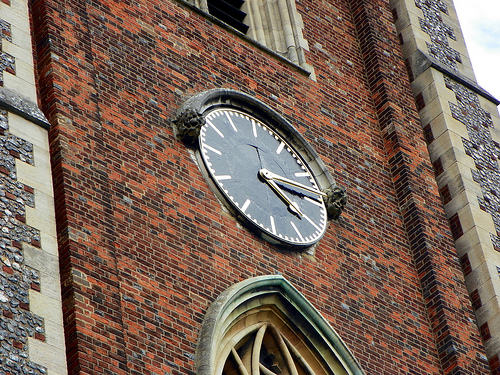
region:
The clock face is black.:
[179, 106, 332, 233]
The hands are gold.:
[257, 168, 318, 220]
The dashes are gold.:
[193, 100, 330, 239]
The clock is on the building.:
[150, 66, 353, 253]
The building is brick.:
[40, 6, 470, 373]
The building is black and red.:
[45, 7, 478, 373]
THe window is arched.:
[178, 266, 353, 373]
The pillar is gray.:
[390, 2, 496, 296]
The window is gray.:
[183, 0, 310, 72]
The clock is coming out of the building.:
[164, 63, 375, 275]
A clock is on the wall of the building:
[162, 66, 357, 250]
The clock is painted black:
[172, 90, 352, 254]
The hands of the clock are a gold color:
[245, 152, 332, 218]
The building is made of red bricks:
[80, 66, 192, 328]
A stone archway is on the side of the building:
[145, 263, 375, 373]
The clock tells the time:
[198, 92, 335, 247]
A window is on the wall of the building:
[200, 1, 318, 76]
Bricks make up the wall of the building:
[92, 183, 184, 268]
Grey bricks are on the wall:
[21, 124, 51, 365]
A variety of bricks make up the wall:
[83, 136, 189, 315]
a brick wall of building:
[59, 17, 177, 116]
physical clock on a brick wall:
[184, 75, 356, 247]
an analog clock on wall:
[189, 90, 336, 250]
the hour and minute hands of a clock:
[254, 163, 328, 221]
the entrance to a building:
[199, 264, 386, 372]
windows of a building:
[137, 3, 324, 80]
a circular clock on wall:
[163, 62, 359, 256]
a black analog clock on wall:
[171, 70, 354, 256]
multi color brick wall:
[79, 122, 167, 274]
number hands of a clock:
[184, 94, 341, 246]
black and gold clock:
[184, 90, 337, 249]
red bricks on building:
[123, 226, 193, 276]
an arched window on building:
[188, 268, 378, 373]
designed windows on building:
[221, 318, 328, 373]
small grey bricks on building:
[476, 158, 498, 190]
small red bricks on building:
[0, 263, 17, 276]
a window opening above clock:
[165, 1, 312, 50]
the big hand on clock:
[259, 170, 324, 195]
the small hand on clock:
[275, 190, 303, 212]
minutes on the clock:
[274, 141, 287, 158]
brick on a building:
[433, 145, 483, 172]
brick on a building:
[433, 160, 478, 188]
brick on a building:
[445, 176, 492, 199]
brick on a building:
[425, 109, 478, 141]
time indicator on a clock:
[246, 113, 261, 140]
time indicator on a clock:
[223, 107, 240, 133]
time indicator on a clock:
[272, 138, 289, 156]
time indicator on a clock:
[290, 167, 316, 179]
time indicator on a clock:
[298, 190, 325, 210]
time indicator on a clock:
[300, 210, 322, 235]